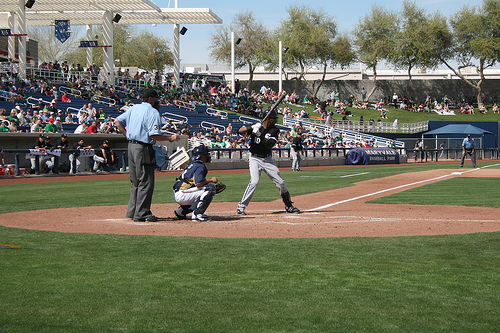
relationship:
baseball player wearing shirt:
[236, 108, 301, 215] [245, 122, 278, 158]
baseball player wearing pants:
[236, 108, 301, 215] [244, 157, 291, 206]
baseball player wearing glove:
[236, 108, 301, 215] [249, 120, 264, 130]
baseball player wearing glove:
[236, 108, 301, 215] [253, 126, 263, 136]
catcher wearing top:
[167, 130, 207, 221] [179, 159, 207, 183]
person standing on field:
[113, 85, 182, 224] [6, 159, 482, 331]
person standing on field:
[234, 113, 299, 220] [6, 159, 482, 331]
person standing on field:
[459, 132, 479, 165] [6, 159, 482, 331]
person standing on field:
[288, 133, 303, 169] [6, 159, 482, 331]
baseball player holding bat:
[236, 108, 301, 215] [242, 89, 297, 128]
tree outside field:
[210, 9, 275, 88] [6, 159, 482, 331]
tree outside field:
[254, 5, 356, 97] [6, 159, 482, 331]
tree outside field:
[346, 5, 408, 80] [6, 159, 482, 331]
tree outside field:
[385, 0, 498, 107] [6, 159, 482, 331]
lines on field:
[316, 170, 483, 300] [365, 152, 498, 231]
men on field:
[1, 53, 378, 153] [6, 159, 482, 331]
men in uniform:
[112, 83, 305, 226] [236, 123, 285, 212]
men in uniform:
[112, 83, 305, 226] [162, 160, 228, 217]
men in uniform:
[112, 83, 305, 226] [106, 103, 168, 220]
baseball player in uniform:
[236, 108, 301, 215] [233, 118, 295, 218]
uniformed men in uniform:
[170, 145, 225, 221] [171, 159, 224, 224]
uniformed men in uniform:
[290, 131, 303, 169] [111, 102, 161, 221]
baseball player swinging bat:
[236, 108, 301, 215] [252, 87, 288, 135]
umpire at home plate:
[111, 86, 182, 223] [273, 203, 325, 216]